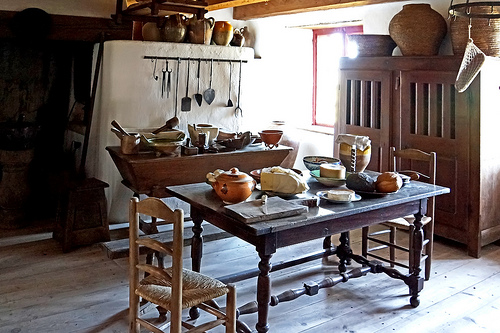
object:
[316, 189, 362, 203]
plate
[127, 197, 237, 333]
chair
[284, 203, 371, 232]
table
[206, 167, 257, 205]
pottery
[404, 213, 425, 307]
wood leg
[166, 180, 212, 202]
table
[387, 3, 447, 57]
basket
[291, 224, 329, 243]
table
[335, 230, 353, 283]
leg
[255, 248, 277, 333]
leg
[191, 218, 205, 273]
leg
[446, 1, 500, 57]
basket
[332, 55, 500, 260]
cabinet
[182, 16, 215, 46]
jars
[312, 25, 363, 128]
window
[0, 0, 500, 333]
kitchen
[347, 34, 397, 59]
basket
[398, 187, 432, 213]
table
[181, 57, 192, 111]
spatula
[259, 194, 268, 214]
knife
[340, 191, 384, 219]
table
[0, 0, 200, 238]
wall